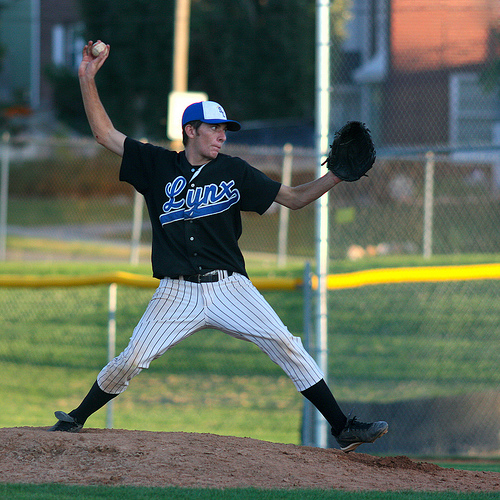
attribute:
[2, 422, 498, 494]
mound — dirt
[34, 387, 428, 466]
shoes — black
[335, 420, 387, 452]
shoes — dark black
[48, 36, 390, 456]
pitcher — in action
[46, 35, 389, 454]
man — blue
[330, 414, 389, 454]
shoe — black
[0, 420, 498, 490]
dirt — brown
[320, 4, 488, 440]
fence — metal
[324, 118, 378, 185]
baseball glove — black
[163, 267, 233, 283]
belt — black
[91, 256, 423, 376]
pants — black, white, striped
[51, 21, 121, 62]
white baseball — red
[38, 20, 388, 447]
player — baseball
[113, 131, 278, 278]
shirt — black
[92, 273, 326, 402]
pants — white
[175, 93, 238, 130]
hat — blue, white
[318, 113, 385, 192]
mitt — black